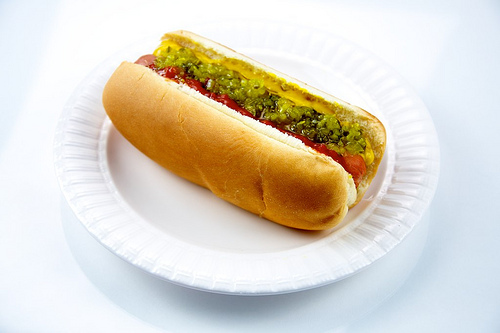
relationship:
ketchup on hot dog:
[145, 59, 352, 174] [101, 29, 385, 231]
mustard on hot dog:
[151, 46, 367, 157] [136, 17, 421, 210]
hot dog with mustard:
[101, 29, 385, 231] [161, 27, 399, 162]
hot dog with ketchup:
[101, 29, 385, 231] [159, 66, 347, 175]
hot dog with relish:
[101, 29, 385, 231] [155, 37, 379, 168]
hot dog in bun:
[101, 29, 385, 231] [242, 162, 333, 232]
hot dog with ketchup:
[101, 29, 385, 231] [274, 122, 345, 160]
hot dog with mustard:
[101, 29, 385, 231] [226, 55, 281, 87]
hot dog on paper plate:
[101, 29, 385, 231] [54, 14, 440, 296]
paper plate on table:
[54, 14, 440, 296] [3, 2, 498, 327]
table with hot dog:
[3, 2, 498, 327] [101, 29, 385, 231]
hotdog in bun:
[347, 155, 367, 184] [242, 134, 355, 234]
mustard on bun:
[151, 46, 367, 157] [101, 26, 387, 233]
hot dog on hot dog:
[131, 53, 364, 183] [101, 29, 385, 231]